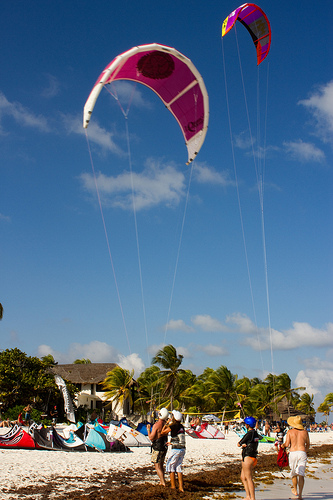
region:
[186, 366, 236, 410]
palm trees blowing in wind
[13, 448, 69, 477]
white sand on beach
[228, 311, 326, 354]
white puffy clouds in the sky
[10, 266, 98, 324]
deep blue skies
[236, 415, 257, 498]
woman in blue helmet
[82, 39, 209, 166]
pink and white wind surf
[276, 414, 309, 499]
man with no top on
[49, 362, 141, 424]
white house on beach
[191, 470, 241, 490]
seaweed gathered on breaker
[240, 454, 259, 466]
orange bikini bottom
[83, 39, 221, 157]
large purple and white arced kite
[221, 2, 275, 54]
high flying multi colored arced kite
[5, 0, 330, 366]
beautiful blue sky with whispy clouds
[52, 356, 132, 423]
white two storied beach dwelling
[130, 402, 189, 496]
two men looking up at purple and white kite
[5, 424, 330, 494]
white sandy beach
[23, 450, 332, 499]
seaweed washed up on the beach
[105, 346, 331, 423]
palm trees being blown by the wind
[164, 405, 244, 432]
yellow volley ball net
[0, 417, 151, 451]
brightly colored kites lying on sandy beach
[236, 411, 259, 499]
A woman wearing a blue helmet.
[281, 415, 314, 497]
A shirtless man wearing a straw hat.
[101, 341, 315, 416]
A bunch of palm trees.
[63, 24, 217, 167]
A purple and white para-sail.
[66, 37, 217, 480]
Two people guiding a para-sail.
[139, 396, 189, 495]
A man and a woman wearing white hats.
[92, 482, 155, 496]
Seaweed that is strewn along the beach.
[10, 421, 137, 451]
A bunch of para-sails clustered together on the beach.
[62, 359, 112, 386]
The roof of a house.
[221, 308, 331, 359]
Fluffy white clouds in the sky.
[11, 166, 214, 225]
White cloud in blue sky.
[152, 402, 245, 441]
Yellow volleyball net on a beach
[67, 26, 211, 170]
A purple para sail in the sky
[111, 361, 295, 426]
Green palm trees in the wind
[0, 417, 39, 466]
Red kayak on the white beach.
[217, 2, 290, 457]
Para sailer pulling in his sail.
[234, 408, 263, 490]
Woman wearing a blue helmet.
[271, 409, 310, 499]
Beachcomber carrying a red bag.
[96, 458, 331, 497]
Green seaweed along the white shoreline.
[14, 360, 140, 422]
Beach house with vegetation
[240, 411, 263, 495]
Lady wearing orange bottom bikini.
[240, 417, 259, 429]
Blue helmet worn by lady in orange bottom bikini.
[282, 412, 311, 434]
Straw hat worn by man in white shorts.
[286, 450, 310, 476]
White shorts worn by man wearing straw hat.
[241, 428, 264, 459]
Black shirt worn by lady in orange bottom bikini.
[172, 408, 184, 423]
White hat worn by guy in black t-shirt.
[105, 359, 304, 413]
Palm trees in center of photo.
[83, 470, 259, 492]
Seaweed man in white hat is standing in.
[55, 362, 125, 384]
Brown roof of white building.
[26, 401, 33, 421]
Man standing in blue shorts next to person with red shirt on.